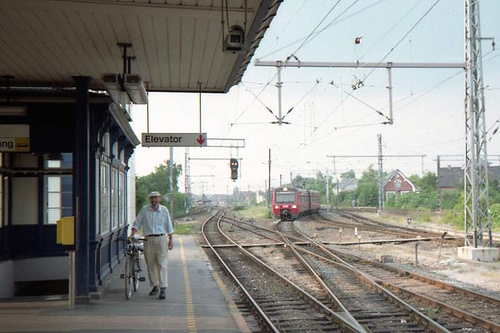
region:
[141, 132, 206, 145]
White sign that says "Elevator".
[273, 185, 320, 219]
Red train coming down the tracks.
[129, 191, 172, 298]
Man rolling his bike down the train platform.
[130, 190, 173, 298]
One man standing on the train platform.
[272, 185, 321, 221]
Train on the train tracks.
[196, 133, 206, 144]
Red arrow on an "Elevator" sign.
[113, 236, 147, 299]
Bicycle next to a man.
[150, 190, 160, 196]
The man is wearing a white hat.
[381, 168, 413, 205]
Brown and white house in the background.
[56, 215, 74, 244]
Yellow box near the platform stair entrance.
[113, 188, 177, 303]
A person walking with his bike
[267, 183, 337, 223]
A red train on the train track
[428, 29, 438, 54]
Part of the blue sky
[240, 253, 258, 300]
Part of the train track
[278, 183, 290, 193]
A light on the front side of the train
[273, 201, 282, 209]
The right headlight of the train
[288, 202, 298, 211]
The left headlight of the train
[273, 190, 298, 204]
The front window of the train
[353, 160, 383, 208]
A big green tree in distance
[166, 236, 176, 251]
The left hand of the person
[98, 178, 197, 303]
man wearing white cap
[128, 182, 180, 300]
man wearing long sleeve dress shirt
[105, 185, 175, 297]
man wearing tan pants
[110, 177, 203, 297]
man holding on to a bicycle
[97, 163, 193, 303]
man wearint brown belt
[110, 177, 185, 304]
man wearing pair of shoes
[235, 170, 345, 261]
red train engine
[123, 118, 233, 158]
the letter e on a sign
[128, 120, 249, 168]
the letter l on a sign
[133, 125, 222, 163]
the letter v on a sign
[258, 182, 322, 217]
The train is red.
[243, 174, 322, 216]
The train is on the tracks.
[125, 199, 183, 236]
The shirt is white.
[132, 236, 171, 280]
The man is wearing tan pants.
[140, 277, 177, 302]
His shoes are black.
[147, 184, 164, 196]
He is wearing a white hat.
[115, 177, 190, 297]
He is walking with a bike.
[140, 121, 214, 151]
The sign is white.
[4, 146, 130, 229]
The windows are open.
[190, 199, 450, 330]
The tracks are brown.